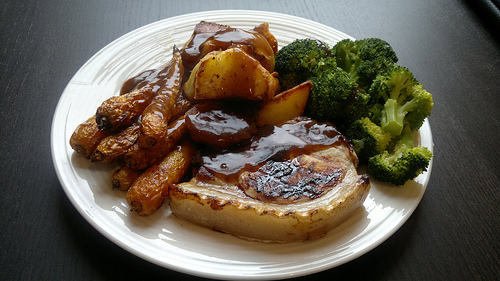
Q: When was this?
A: Daytime.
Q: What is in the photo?
A: Food.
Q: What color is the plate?
A: White.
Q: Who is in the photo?
A: Nobody.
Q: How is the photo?
A: Clear.